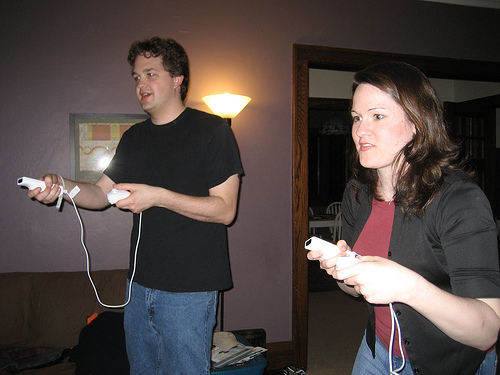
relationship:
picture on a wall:
[69, 111, 149, 186] [1, 2, 296, 339]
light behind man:
[202, 93, 252, 120] [26, 39, 245, 374]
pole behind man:
[221, 293, 225, 332] [26, 39, 245, 374]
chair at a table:
[332, 209, 343, 248] [308, 212, 343, 243]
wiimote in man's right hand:
[17, 177, 65, 208] [30, 173, 65, 208]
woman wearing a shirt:
[306, 62, 496, 374] [352, 196, 409, 360]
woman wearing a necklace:
[306, 62, 496, 374] [376, 177, 397, 205]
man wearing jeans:
[26, 39, 245, 374] [122, 276, 219, 374]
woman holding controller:
[306, 62, 496, 374] [305, 236, 407, 374]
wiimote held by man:
[17, 177, 65, 208] [26, 39, 245, 374]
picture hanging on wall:
[69, 111, 149, 186] [1, 2, 296, 339]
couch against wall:
[0, 272, 132, 374] [1, 2, 296, 339]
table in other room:
[308, 212, 343, 243] [310, 197, 499, 374]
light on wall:
[202, 93, 252, 120] [1, 2, 296, 339]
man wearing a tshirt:
[26, 39, 245, 374] [105, 107, 234, 293]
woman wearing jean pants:
[306, 62, 496, 374] [350, 328, 496, 374]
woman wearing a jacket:
[306, 62, 496, 374] [337, 177, 499, 374]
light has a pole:
[202, 93, 252, 120] [221, 293, 225, 332]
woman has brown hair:
[306, 62, 496, 374] [351, 60, 475, 214]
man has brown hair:
[26, 39, 245, 374] [128, 37, 190, 100]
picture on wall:
[69, 111, 149, 186] [1, 2, 296, 339]